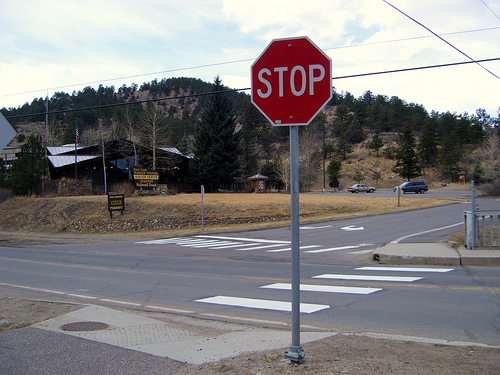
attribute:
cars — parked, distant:
[348, 181, 429, 197]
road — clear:
[222, 203, 468, 276]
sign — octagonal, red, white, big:
[245, 36, 334, 129]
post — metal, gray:
[286, 130, 308, 364]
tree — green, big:
[191, 75, 251, 189]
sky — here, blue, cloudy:
[5, 3, 499, 103]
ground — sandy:
[264, 338, 499, 375]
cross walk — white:
[197, 259, 436, 324]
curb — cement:
[362, 237, 492, 277]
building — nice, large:
[46, 137, 194, 191]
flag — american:
[71, 119, 82, 144]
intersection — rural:
[63, 229, 381, 328]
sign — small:
[106, 193, 129, 216]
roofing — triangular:
[49, 154, 95, 170]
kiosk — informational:
[246, 172, 271, 193]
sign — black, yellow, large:
[127, 165, 167, 191]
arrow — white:
[341, 220, 364, 238]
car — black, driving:
[396, 179, 430, 196]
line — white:
[267, 272, 382, 302]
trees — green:
[70, 85, 133, 122]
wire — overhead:
[349, 57, 480, 80]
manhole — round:
[55, 317, 111, 341]